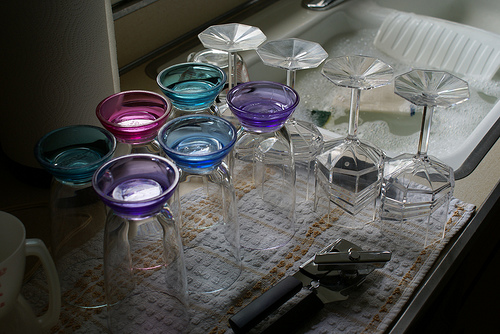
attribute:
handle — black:
[230, 272, 321, 332]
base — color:
[149, 57, 229, 111]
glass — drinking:
[155, 55, 226, 113]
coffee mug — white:
[2, 212, 63, 328]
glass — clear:
[226, 81, 296, 251]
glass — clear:
[319, 54, 384, 230]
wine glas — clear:
[366, 65, 471, 251]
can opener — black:
[230, 235, 390, 331]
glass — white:
[382, 62, 472, 245]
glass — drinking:
[90, 152, 180, 331]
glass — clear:
[318, 55, 395, 227]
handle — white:
[11, 236, 65, 330]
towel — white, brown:
[11, 152, 479, 329]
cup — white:
[0, 203, 67, 330]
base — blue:
[181, 125, 227, 157]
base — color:
[91, 152, 179, 212]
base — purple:
[226, 79, 301, 130]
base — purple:
[90, 152, 180, 218]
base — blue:
[154, 112, 238, 168]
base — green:
[34, 120, 117, 183]